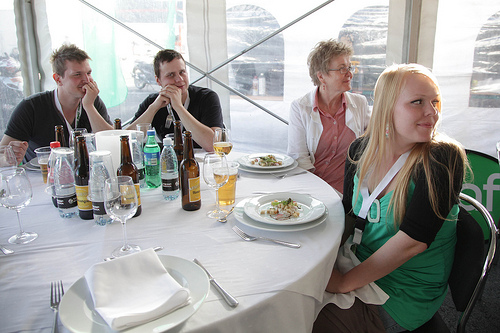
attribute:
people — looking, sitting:
[0, 40, 464, 331]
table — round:
[4, 154, 337, 332]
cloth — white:
[0, 148, 346, 333]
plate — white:
[233, 190, 329, 232]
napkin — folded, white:
[82, 247, 191, 328]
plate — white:
[59, 253, 210, 332]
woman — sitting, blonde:
[316, 63, 467, 332]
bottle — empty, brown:
[177, 132, 204, 213]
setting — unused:
[42, 241, 246, 332]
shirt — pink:
[312, 96, 359, 188]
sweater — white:
[290, 93, 370, 171]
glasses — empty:
[1, 131, 141, 232]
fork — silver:
[233, 223, 302, 250]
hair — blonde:
[347, 63, 475, 224]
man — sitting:
[127, 49, 227, 153]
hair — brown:
[150, 49, 190, 78]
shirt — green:
[337, 132, 480, 328]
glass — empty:
[3, 171, 45, 246]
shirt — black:
[139, 87, 233, 144]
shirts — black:
[4, 88, 227, 163]